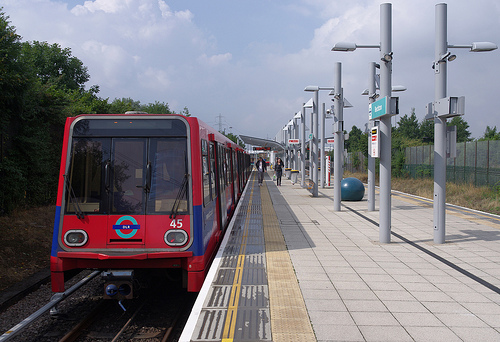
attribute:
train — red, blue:
[41, 104, 257, 301]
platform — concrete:
[235, 178, 500, 341]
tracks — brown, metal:
[13, 282, 175, 342]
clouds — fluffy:
[40, 4, 496, 88]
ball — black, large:
[340, 173, 368, 205]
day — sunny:
[4, 4, 498, 340]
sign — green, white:
[363, 94, 394, 125]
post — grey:
[429, 1, 451, 244]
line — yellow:
[230, 196, 254, 337]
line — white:
[183, 256, 223, 337]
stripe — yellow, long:
[254, 179, 311, 336]